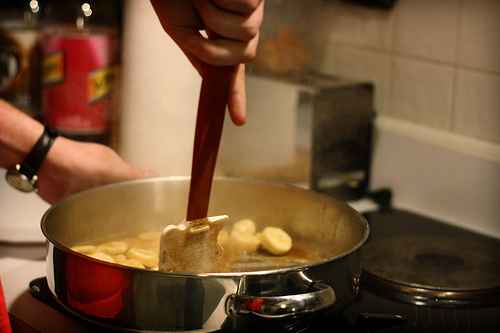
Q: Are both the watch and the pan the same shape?
A: Yes, both the watch and the pan are round.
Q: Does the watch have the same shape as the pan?
A: Yes, both the watch and the pan are round.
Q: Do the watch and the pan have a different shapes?
A: No, both the watch and the pan are round.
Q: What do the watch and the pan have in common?
A: The shape, both the watch and the pan are round.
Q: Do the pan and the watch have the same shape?
A: Yes, both the pan and the watch are round.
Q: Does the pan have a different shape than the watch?
A: No, both the pan and the watch are round.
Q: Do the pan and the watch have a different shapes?
A: No, both the pan and the watch are round.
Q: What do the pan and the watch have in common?
A: The shape, both the pan and the watch are round.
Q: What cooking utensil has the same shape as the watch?
A: The pan is the same shape as the watch.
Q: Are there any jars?
A: No, there are no jars.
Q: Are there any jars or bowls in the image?
A: No, there are no jars or bowls.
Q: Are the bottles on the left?
A: Yes, the bottles are on the left of the image.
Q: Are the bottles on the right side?
A: No, the bottles are on the left of the image.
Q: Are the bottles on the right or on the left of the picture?
A: The bottles are on the left of the image.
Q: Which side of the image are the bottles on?
A: The bottles are on the left of the image.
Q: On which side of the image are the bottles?
A: The bottles are on the left of the image.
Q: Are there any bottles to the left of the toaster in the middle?
A: Yes, there are bottles to the left of the toaster.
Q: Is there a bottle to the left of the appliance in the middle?
A: Yes, there are bottles to the left of the toaster.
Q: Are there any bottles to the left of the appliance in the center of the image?
A: Yes, there are bottles to the left of the toaster.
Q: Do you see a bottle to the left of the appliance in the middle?
A: Yes, there are bottles to the left of the toaster.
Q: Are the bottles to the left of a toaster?
A: Yes, the bottles are to the left of a toaster.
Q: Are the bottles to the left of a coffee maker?
A: No, the bottles are to the left of a toaster.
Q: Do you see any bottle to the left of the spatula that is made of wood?
A: Yes, there are bottles to the left of the spatula.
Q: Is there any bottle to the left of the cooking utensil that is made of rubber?
A: Yes, there are bottles to the left of the spatula.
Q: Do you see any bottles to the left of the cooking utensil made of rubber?
A: Yes, there are bottles to the left of the spatula.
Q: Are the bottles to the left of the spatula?
A: Yes, the bottles are to the left of the spatula.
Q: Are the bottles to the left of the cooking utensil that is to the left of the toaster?
A: Yes, the bottles are to the left of the spatula.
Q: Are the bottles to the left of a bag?
A: No, the bottles are to the left of the spatula.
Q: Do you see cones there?
A: No, there are no cones.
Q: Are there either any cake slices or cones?
A: No, there are no cones or cake slices.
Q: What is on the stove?
A: The stove burner is on the stove.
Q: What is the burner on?
A: The burner is on the stove.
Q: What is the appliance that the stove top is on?
A: The appliance is a stove.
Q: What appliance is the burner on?
A: The stove top is on the stove.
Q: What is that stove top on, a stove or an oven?
A: The stove top is on a stove.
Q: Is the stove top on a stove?
A: Yes, the stove top is on a stove.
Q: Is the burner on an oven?
A: No, the burner is on a stove.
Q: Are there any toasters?
A: Yes, there is a toaster.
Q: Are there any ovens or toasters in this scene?
A: Yes, there is a toaster.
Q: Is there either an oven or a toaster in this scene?
A: Yes, there is a toaster.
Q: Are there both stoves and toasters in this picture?
A: Yes, there are both a toaster and a stove.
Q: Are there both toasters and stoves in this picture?
A: Yes, there are both a toaster and a stove.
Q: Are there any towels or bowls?
A: No, there are no bowls or towels.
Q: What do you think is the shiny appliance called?
A: The appliance is a toaster.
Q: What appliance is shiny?
A: The appliance is a toaster.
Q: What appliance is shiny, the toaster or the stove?
A: The toaster is shiny.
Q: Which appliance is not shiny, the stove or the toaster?
A: The stove is not shiny.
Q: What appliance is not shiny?
A: The appliance is a stove.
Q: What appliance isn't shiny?
A: The appliance is a stove.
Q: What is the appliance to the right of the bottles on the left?
A: The appliance is a toaster.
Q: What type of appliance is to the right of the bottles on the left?
A: The appliance is a toaster.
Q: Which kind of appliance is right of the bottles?
A: The appliance is a toaster.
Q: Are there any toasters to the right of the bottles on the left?
A: Yes, there is a toaster to the right of the bottles.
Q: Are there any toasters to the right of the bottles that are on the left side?
A: Yes, there is a toaster to the right of the bottles.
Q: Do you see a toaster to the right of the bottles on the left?
A: Yes, there is a toaster to the right of the bottles.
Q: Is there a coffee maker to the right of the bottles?
A: No, there is a toaster to the right of the bottles.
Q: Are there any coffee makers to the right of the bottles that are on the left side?
A: No, there is a toaster to the right of the bottles.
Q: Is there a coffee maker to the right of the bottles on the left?
A: No, there is a toaster to the right of the bottles.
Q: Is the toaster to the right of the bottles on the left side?
A: Yes, the toaster is to the right of the bottles.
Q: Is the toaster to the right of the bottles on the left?
A: Yes, the toaster is to the right of the bottles.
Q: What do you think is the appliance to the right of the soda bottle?
A: The appliance is a toaster.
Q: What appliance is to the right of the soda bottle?
A: The appliance is a toaster.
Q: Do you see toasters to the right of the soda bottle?
A: Yes, there is a toaster to the right of the soda bottle.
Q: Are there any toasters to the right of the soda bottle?
A: Yes, there is a toaster to the right of the soda bottle.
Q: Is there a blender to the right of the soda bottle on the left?
A: No, there is a toaster to the right of the soda bottle.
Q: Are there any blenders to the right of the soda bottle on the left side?
A: No, there is a toaster to the right of the soda bottle.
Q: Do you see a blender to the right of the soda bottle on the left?
A: No, there is a toaster to the right of the soda bottle.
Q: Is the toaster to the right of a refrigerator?
A: No, the toaster is to the right of the soda bottle.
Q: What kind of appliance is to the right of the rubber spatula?
A: The appliance is a toaster.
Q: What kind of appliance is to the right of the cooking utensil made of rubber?
A: The appliance is a toaster.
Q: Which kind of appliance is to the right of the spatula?
A: The appliance is a toaster.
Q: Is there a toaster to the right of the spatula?
A: Yes, there is a toaster to the right of the spatula.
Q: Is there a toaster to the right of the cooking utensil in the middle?
A: Yes, there is a toaster to the right of the spatula.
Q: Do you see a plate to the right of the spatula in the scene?
A: No, there is a toaster to the right of the spatula.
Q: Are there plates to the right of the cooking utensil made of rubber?
A: No, there is a toaster to the right of the spatula.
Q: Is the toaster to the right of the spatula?
A: Yes, the toaster is to the right of the spatula.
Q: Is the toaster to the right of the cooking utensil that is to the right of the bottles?
A: Yes, the toaster is to the right of the spatula.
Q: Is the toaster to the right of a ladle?
A: No, the toaster is to the right of the spatula.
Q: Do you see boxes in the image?
A: No, there are no boxes.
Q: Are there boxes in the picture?
A: No, there are no boxes.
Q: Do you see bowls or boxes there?
A: No, there are no boxes or bowls.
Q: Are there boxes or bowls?
A: No, there are no boxes or bowls.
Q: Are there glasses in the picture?
A: No, there are no glasses.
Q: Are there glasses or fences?
A: No, there are no glasses or fences.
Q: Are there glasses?
A: No, there are no glasses.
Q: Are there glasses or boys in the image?
A: No, there are no glasses or boys.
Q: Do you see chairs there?
A: No, there are no chairs.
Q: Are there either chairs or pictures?
A: No, there are no chairs or pictures.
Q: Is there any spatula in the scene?
A: Yes, there is a spatula.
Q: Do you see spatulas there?
A: Yes, there is a spatula.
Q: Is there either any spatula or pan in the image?
A: Yes, there is a spatula.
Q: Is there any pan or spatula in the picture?
A: Yes, there is a spatula.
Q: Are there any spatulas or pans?
A: Yes, there is a spatula.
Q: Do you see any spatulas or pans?
A: Yes, there is a spatula.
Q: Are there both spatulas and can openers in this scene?
A: No, there is a spatula but no can openers.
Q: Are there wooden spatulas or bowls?
A: Yes, there is a wood spatula.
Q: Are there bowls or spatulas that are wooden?
A: Yes, the spatula is wooden.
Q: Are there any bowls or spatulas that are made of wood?
A: Yes, the spatula is made of wood.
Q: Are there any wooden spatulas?
A: Yes, there is a wood spatula.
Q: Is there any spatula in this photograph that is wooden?
A: Yes, there is a spatula that is wooden.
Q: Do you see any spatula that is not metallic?
A: Yes, there is a wooden spatula.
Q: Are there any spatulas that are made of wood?
A: Yes, there is a spatula that is made of wood.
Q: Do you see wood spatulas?
A: Yes, there is a spatula that is made of wood.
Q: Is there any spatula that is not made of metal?
A: Yes, there is a spatula that is made of wood.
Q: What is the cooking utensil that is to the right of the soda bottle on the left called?
A: The cooking utensil is a spatula.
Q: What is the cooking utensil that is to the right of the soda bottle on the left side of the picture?
A: The cooking utensil is a spatula.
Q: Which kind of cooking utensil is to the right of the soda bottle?
A: The cooking utensil is a spatula.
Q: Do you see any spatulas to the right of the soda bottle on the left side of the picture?
A: Yes, there is a spatula to the right of the soda bottle.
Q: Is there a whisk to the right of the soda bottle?
A: No, there is a spatula to the right of the soda bottle.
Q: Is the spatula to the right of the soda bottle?
A: Yes, the spatula is to the right of the soda bottle.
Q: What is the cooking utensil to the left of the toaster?
A: The cooking utensil is a spatula.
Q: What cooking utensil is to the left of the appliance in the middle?
A: The cooking utensil is a spatula.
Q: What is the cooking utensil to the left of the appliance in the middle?
A: The cooking utensil is a spatula.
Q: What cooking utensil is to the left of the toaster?
A: The cooking utensil is a spatula.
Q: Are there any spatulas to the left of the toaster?
A: Yes, there is a spatula to the left of the toaster.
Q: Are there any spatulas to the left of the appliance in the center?
A: Yes, there is a spatula to the left of the toaster.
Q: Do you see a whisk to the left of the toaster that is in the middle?
A: No, there is a spatula to the left of the toaster.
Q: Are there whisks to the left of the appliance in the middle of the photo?
A: No, there is a spatula to the left of the toaster.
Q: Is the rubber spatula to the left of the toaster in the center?
A: Yes, the spatula is to the left of the toaster.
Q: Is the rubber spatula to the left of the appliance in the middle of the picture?
A: Yes, the spatula is to the left of the toaster.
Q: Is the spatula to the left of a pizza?
A: No, the spatula is to the left of the toaster.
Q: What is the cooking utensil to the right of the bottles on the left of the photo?
A: The cooking utensil is a spatula.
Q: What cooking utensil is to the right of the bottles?
A: The cooking utensil is a spatula.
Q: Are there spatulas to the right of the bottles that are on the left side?
A: Yes, there is a spatula to the right of the bottles.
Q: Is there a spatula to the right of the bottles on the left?
A: Yes, there is a spatula to the right of the bottles.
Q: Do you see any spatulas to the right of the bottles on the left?
A: Yes, there is a spatula to the right of the bottles.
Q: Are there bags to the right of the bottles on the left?
A: No, there is a spatula to the right of the bottles.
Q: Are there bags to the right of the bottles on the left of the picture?
A: No, there is a spatula to the right of the bottles.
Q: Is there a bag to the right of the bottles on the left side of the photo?
A: No, there is a spatula to the right of the bottles.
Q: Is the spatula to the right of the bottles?
A: Yes, the spatula is to the right of the bottles.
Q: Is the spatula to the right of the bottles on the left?
A: Yes, the spatula is to the right of the bottles.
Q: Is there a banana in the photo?
A: Yes, there is a banana.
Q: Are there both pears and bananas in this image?
A: No, there is a banana but no pears.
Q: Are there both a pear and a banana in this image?
A: No, there is a banana but no pears.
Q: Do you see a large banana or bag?
A: Yes, there is a large banana.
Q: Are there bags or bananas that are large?
A: Yes, the banana is large.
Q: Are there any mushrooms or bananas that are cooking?
A: Yes, the banana is cooking.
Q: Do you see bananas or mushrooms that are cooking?
A: Yes, the banana is cooking.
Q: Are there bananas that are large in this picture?
A: Yes, there is a large banana.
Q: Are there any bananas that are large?
A: Yes, there is a banana that is large.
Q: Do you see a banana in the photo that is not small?
A: Yes, there is a large banana.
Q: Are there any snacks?
A: No, there are no snacks.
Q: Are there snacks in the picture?
A: No, there are no snacks.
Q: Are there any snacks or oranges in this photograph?
A: No, there are no snacks or oranges.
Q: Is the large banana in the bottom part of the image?
A: Yes, the banana is in the bottom of the image.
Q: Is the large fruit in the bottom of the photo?
A: Yes, the banana is in the bottom of the image.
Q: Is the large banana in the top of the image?
A: No, the banana is in the bottom of the image.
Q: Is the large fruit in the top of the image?
A: No, the banana is in the bottom of the image.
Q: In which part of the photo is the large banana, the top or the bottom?
A: The banana is in the bottom of the image.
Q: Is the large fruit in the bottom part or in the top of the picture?
A: The banana is in the bottom of the image.